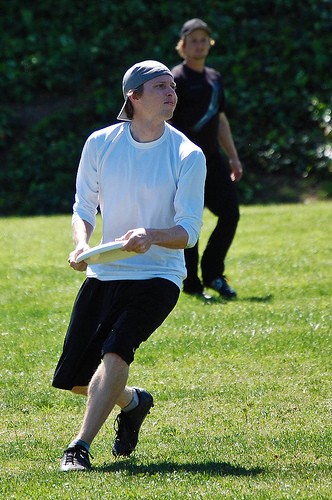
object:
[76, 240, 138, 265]
frisbee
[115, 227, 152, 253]
hand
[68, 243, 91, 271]
hand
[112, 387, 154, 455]
cleat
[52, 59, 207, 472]
man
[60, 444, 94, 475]
cleat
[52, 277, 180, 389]
shorts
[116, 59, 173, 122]
hat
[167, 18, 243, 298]
man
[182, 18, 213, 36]
hat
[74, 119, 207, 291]
shirt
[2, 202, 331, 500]
grass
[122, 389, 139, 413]
sock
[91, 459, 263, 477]
shadow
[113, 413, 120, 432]
lace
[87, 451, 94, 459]
lace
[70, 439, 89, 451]
sock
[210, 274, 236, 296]
shoe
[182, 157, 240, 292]
pants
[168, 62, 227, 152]
shirt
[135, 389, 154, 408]
heel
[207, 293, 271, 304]
shadow